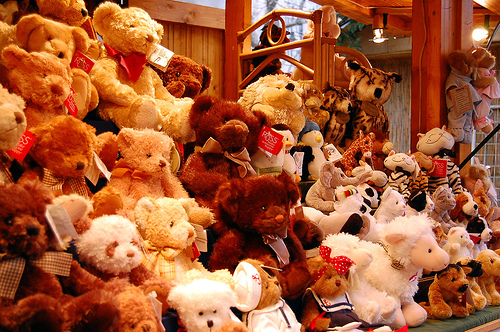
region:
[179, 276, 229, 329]
the bear is white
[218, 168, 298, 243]
the bear is brown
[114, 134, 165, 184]
the bear is light brown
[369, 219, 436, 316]
the lamb is white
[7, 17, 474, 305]
there are many stuffed animals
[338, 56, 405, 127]
the owl has spots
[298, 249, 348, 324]
the bear has a bow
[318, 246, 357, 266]
the bow is red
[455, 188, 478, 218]
the dog is brown and white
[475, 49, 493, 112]
the bear has a pink dress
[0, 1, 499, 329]
many stuffed toys arranged together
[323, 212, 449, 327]
a white toy sheep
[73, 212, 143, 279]
a stuffed toy panda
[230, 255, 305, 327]
a toy bear dressed as a sailor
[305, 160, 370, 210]
a small toy elephant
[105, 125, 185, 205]
a toy bear with a brown bow around its neck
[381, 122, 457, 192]
stuffed toys with tiger-like stripes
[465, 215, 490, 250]
a black and white toy dog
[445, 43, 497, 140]
toy bears wearing blue and pink outfits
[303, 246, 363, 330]
a toy bear with a polka-dot bow on its head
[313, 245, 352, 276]
Red and white bow on bear's head.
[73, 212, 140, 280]
White teddy bear with brown eye spots.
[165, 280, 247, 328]
All white teddy bear head.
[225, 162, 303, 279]
Big brown teddy bear in the middle.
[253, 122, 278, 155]
Red and white sign hanging from bear.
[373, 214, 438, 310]
Big white sheep teddy bear.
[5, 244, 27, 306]
Checkered tie around bear's neck.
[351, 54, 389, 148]
Big lion with spot bear in the back.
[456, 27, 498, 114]
Two bears hanging from the wall.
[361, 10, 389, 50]
Small light fixture in the back.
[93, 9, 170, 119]
Beautil brown teddy bear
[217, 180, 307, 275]
Beautil brown teddy bear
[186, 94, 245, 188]
Beautil brown teddy bear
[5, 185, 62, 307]
Beautil brown teddy bear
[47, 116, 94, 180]
Beautil brown teddy bear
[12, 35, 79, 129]
Beautil brown teddy bear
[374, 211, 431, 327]
Beautil white teddy bear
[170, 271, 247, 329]
Beautil white teddy bear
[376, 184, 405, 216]
Beautil white teddy bear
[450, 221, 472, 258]
Beautil white teddy bear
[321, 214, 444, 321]
white stuffed sheep on the table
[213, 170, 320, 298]
large brown bear on the table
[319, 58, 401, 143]
stuffed spotted owls on the table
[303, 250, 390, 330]
teddy bear in a dress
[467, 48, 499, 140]
bear wearing a pink outfit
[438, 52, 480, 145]
bear wearing a light blue outfit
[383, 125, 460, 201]
stuffed cats on the table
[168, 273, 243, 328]
white teddy bear on the table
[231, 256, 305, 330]
teddy bear in a sailor outfit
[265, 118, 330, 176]
stuffed penguins on the table